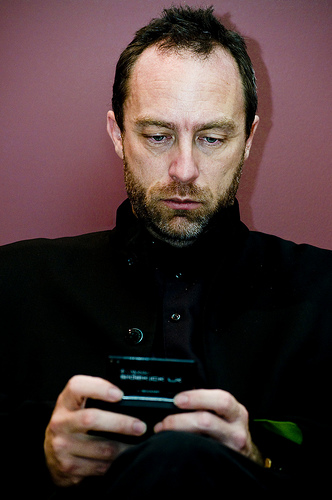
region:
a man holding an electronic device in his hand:
[23, 8, 309, 487]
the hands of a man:
[43, 375, 257, 487]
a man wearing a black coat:
[10, 9, 328, 346]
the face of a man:
[139, 113, 226, 218]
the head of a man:
[105, 6, 263, 239]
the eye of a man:
[196, 130, 226, 150]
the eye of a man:
[142, 128, 178, 153]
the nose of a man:
[166, 151, 201, 183]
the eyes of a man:
[142, 127, 229, 147]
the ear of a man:
[96, 104, 131, 168]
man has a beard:
[84, 13, 275, 248]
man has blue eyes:
[100, 6, 263, 261]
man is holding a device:
[32, 286, 274, 487]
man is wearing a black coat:
[4, 183, 327, 495]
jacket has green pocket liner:
[238, 387, 323, 478]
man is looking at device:
[40, 11, 279, 485]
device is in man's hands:
[47, 287, 263, 497]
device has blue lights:
[97, 308, 202, 454]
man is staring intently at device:
[3, 5, 329, 496]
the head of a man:
[59, 24, 268, 260]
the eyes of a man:
[122, 118, 268, 172]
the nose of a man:
[155, 139, 221, 194]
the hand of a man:
[33, 342, 202, 479]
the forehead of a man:
[140, 26, 250, 119]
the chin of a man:
[138, 221, 230, 257]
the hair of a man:
[103, 19, 249, 176]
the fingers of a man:
[47, 351, 215, 465]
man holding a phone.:
[81, 345, 219, 437]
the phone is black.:
[89, 319, 199, 427]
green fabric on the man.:
[250, 404, 308, 449]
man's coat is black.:
[1, 223, 327, 496]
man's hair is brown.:
[103, 4, 261, 144]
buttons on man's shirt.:
[159, 265, 191, 335]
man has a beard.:
[118, 155, 247, 237]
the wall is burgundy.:
[1, 0, 330, 252]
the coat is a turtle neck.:
[108, 187, 249, 246]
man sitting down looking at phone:
[19, 30, 319, 478]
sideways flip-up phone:
[78, 343, 221, 434]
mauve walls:
[3, 1, 324, 239]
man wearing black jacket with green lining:
[0, 208, 321, 476]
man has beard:
[119, 155, 236, 238]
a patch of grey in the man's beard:
[178, 219, 200, 242]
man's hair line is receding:
[151, 40, 226, 57]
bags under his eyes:
[138, 138, 228, 150]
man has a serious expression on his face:
[108, 12, 261, 240]